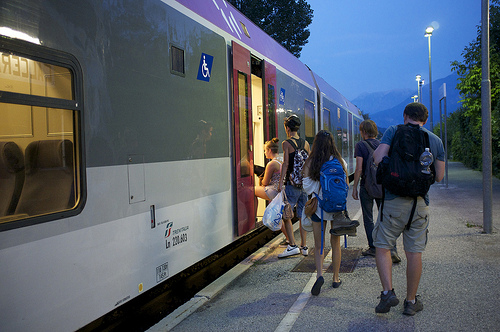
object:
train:
[1, 0, 366, 332]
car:
[0, 0, 364, 331]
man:
[371, 102, 445, 317]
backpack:
[375, 122, 436, 198]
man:
[351, 119, 401, 263]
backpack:
[362, 140, 386, 199]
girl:
[302, 130, 359, 296]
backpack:
[314, 157, 349, 213]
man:
[278, 115, 311, 259]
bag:
[263, 189, 285, 231]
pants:
[372, 196, 429, 253]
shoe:
[375, 288, 400, 313]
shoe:
[403, 295, 424, 316]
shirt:
[379, 125, 445, 206]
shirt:
[354, 138, 380, 187]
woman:
[254, 138, 292, 248]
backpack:
[285, 138, 309, 189]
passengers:
[254, 102, 445, 315]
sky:
[296, 0, 482, 101]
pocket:
[421, 171, 432, 196]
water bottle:
[420, 148, 434, 175]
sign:
[197, 52, 214, 82]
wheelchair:
[202, 56, 211, 78]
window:
[0, 35, 89, 236]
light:
[424, 27, 434, 38]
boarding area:
[143, 161, 500, 332]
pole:
[481, 0, 494, 233]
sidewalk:
[140, 161, 500, 332]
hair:
[403, 102, 429, 122]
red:
[391, 172, 400, 177]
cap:
[283, 114, 301, 128]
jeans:
[359, 186, 397, 252]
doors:
[231, 42, 279, 236]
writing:
[272, 205, 285, 229]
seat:
[13, 139, 74, 217]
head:
[359, 119, 379, 140]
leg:
[360, 181, 375, 248]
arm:
[352, 144, 363, 191]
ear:
[404, 113, 407, 120]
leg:
[255, 186, 277, 218]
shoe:
[311, 276, 324, 296]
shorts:
[265, 185, 280, 201]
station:
[145, 0, 500, 332]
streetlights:
[411, 0, 497, 235]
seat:
[1, 141, 23, 216]